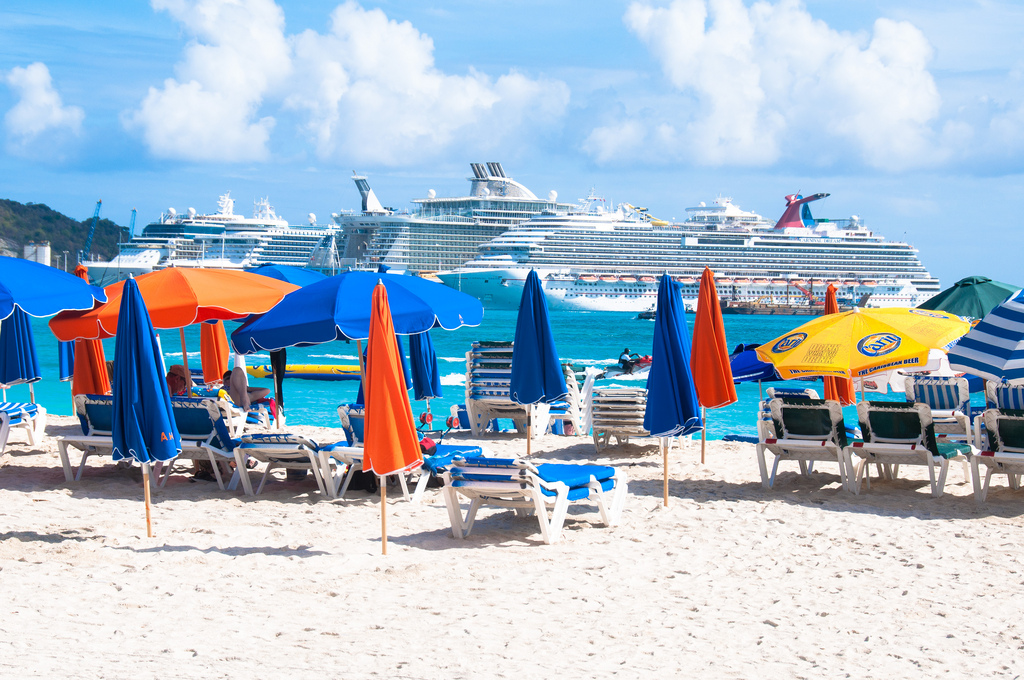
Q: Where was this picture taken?
A: At the beach.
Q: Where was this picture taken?
A: At the beach.